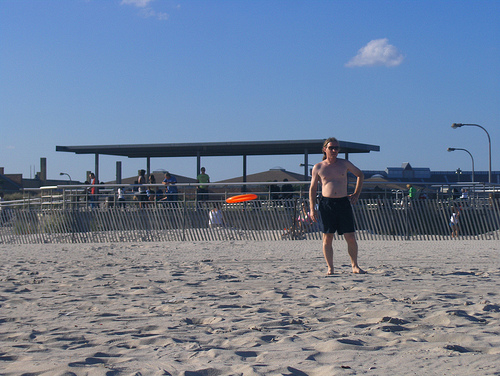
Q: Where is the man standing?
A: Sand.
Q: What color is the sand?
A: Brown.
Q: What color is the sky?
A: Blue.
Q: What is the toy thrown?
A: Frisbee.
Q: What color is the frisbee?
A: Orange.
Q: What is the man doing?
A: Standing.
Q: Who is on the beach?
A: Man.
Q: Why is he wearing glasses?
A: Sun.